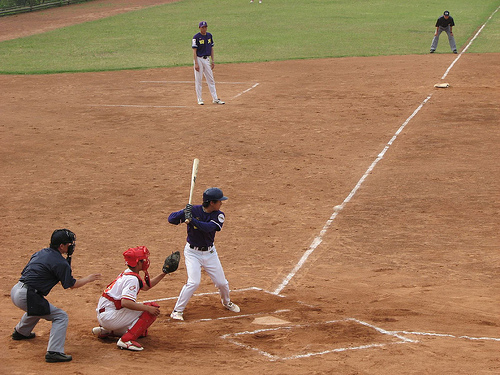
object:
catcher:
[10, 229, 97, 360]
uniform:
[9, 249, 74, 345]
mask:
[65, 230, 76, 263]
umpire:
[428, 7, 458, 56]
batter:
[169, 158, 240, 320]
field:
[3, 7, 499, 374]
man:
[188, 21, 226, 104]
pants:
[192, 58, 220, 100]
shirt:
[434, 18, 453, 29]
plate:
[250, 315, 291, 326]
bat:
[185, 157, 201, 224]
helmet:
[202, 188, 227, 201]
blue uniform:
[168, 207, 226, 249]